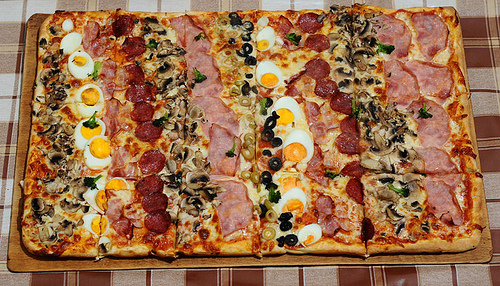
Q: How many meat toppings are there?
A: Two.